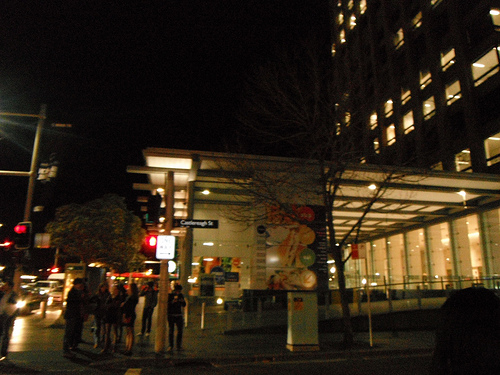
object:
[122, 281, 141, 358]
person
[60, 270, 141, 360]
group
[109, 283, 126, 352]
person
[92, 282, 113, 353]
person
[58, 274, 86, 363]
person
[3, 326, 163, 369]
street corner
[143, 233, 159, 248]
stop light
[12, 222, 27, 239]
stop light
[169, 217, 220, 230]
street sign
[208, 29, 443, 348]
tree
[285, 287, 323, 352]
electrical box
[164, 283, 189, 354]
woman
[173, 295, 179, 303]
cup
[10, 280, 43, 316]
car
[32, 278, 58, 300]
car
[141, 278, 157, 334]
person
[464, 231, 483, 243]
light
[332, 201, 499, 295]
lobby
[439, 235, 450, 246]
light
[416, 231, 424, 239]
light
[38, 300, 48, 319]
trash can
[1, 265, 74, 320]
street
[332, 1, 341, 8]
upper window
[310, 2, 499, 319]
building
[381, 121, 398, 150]
window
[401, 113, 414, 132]
window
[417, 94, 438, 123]
window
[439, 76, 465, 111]
window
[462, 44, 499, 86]
window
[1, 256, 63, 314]
traffic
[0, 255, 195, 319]
distance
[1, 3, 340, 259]
sky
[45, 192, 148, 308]
tree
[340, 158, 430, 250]
branch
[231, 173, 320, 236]
branch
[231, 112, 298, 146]
branch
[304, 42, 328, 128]
branch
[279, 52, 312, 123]
branch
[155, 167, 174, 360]
post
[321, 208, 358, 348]
trunk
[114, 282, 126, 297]
hair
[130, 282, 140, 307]
hair